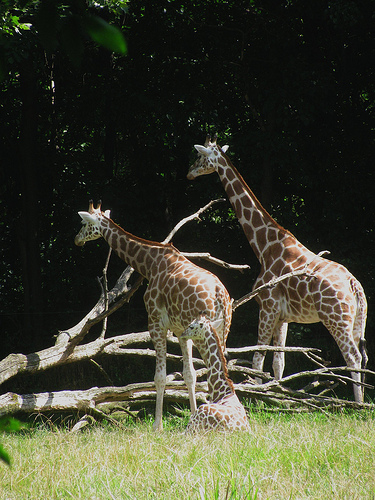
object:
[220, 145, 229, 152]
ear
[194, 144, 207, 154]
ear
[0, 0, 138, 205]
green leaves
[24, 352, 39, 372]
shadow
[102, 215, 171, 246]
mane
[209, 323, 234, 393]
mane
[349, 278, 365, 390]
giraffe tail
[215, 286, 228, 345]
giraffe tail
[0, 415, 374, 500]
grass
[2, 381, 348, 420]
logs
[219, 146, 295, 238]
brown mane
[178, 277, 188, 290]
spots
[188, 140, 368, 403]
giraffe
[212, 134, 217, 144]
horns.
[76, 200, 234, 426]
giraffe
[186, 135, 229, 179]
head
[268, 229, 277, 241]
fur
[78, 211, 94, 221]
ear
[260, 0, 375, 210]
tree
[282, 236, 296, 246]
spots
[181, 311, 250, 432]
giraffe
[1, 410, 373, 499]
field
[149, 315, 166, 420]
legs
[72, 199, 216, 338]
branches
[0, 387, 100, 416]
tree trunk